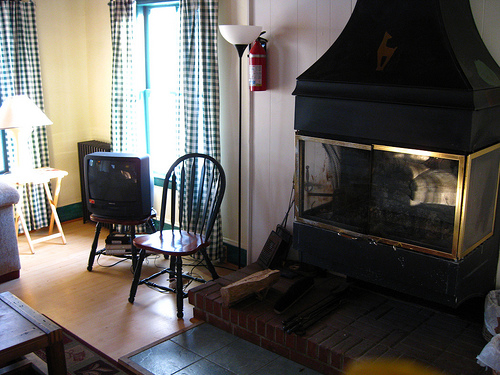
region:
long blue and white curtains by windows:
[2, 5, 222, 267]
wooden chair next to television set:
[75, 145, 226, 322]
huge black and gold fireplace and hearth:
[130, 5, 492, 365]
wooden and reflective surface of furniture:
[1, 285, 132, 366]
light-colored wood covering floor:
[1, 210, 231, 355]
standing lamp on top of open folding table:
[1, 88, 66, 254]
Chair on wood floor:
[132, 144, 237, 337]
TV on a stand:
[76, 145, 156, 223]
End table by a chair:
[2, 162, 72, 253]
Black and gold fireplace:
[273, 58, 499, 311]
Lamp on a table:
[4, 91, 64, 172]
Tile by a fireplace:
[89, 312, 366, 372]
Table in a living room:
[3, 287, 65, 374]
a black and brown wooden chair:
[122, 152, 227, 316]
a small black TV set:
[82, 148, 153, 219]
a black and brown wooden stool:
[85, 208, 159, 271]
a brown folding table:
[5, 166, 67, 250]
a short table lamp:
[1, 93, 52, 173]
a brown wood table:
[0, 290, 67, 372]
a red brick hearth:
[188, 261, 496, 371]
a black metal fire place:
[291, 0, 496, 305]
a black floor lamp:
[216, 22, 262, 277]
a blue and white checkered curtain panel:
[176, 1, 222, 269]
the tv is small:
[85, 156, 153, 226]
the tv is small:
[69, 153, 151, 227]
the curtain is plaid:
[99, 3, 154, 194]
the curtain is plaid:
[157, 7, 230, 252]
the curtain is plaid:
[8, 16, 59, 217]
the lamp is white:
[3, 96, 59, 176]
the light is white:
[211, 23, 258, 65]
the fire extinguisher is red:
[247, 38, 276, 99]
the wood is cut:
[213, 254, 278, 313]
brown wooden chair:
[122, 141, 228, 342]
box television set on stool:
[83, 146, 168, 276]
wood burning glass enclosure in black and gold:
[295, 126, 491, 324]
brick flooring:
[185, 241, 499, 373]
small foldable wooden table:
[9, 164, 70, 256]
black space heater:
[76, 135, 114, 224]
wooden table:
[2, 285, 65, 374]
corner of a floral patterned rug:
[26, 306, 136, 373]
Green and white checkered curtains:
[107, 0, 226, 263]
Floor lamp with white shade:
[217, 20, 259, 267]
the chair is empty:
[134, 148, 222, 290]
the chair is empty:
[123, 143, 216, 316]